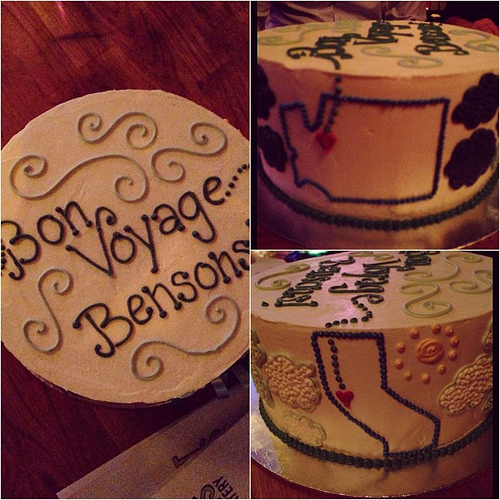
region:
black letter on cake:
[1, 214, 44, 279]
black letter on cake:
[23, 210, 68, 245]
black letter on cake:
[43, 195, 96, 239]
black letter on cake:
[56, 196, 118, 281]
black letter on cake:
[107, 223, 143, 272]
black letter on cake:
[116, 205, 162, 275]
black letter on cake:
[145, 199, 191, 239]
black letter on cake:
[169, 181, 219, 252]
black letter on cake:
[188, 165, 228, 213]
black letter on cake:
[59, 285, 139, 367]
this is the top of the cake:
[1, 74, 280, 425]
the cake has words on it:
[4, 117, 269, 394]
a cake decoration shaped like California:
[286, 323, 473, 474]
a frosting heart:
[330, 371, 361, 417]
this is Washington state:
[276, 70, 457, 220]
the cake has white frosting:
[3, 76, 264, 421]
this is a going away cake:
[0, 0, 490, 497]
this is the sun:
[380, 310, 480, 396]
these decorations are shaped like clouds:
[246, 323, 334, 456]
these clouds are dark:
[442, 70, 499, 200]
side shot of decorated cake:
[255, 17, 499, 233]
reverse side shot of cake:
[251, 250, 497, 470]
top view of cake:
[0, 87, 249, 404]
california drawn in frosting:
[311, 327, 442, 457]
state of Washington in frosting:
[278, 90, 448, 206]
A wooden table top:
[0, 0, 245, 495]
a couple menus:
[52, 376, 247, 496]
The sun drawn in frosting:
[391, 320, 456, 380]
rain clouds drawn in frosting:
[251, 60, 496, 190]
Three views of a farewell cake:
[1, 2, 498, 499]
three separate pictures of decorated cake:
[0, 1, 495, 497]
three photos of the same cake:
[0, 1, 495, 496]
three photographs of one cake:
[0, 1, 495, 493]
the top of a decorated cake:
[250, 250, 491, 331]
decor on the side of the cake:
[250, 328, 495, 470]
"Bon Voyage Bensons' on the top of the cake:
[0, 87, 247, 402]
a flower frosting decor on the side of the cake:
[263, 351, 321, 411]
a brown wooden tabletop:
[5, 4, 248, 86]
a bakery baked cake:
[0, 3, 247, 497]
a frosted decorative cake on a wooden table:
[2, 5, 249, 410]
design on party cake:
[5, 139, 153, 209]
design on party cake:
[71, 90, 160, 152]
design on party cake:
[146, 104, 231, 187]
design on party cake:
[18, 260, 79, 356]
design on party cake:
[126, 287, 241, 382]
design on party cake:
[380, 303, 467, 391]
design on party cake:
[257, 347, 321, 421]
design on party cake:
[434, 337, 492, 415]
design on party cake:
[393, 270, 451, 327]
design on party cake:
[401, 233, 488, 300]